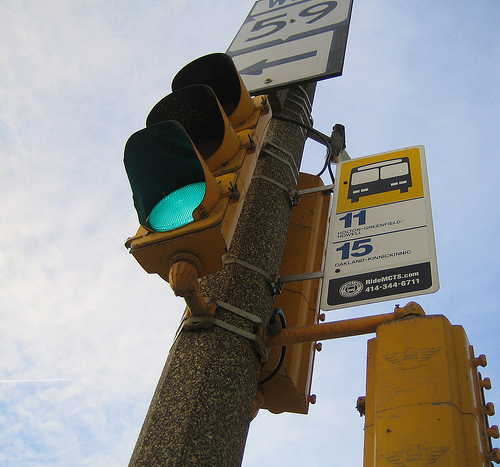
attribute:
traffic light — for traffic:
[123, 53, 274, 316]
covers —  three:
[123, 119, 217, 231]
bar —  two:
[285, 183, 334, 195]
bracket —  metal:
[224, 253, 272, 281]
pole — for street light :
[126, 82, 314, 464]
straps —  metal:
[225, 173, 285, 286]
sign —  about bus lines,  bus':
[318, 143, 438, 311]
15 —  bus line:
[332, 236, 372, 260]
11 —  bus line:
[337, 209, 368, 228]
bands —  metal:
[181, 300, 270, 359]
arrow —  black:
[235, 50, 318, 75]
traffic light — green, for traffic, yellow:
[99, 52, 282, 312]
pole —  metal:
[125, 344, 275, 465]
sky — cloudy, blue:
[3, 3, 129, 120]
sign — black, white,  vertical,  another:
[230, 4, 351, 82]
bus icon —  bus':
[343, 152, 420, 208]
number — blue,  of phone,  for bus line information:
[339, 206, 368, 231]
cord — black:
[279, 112, 337, 180]